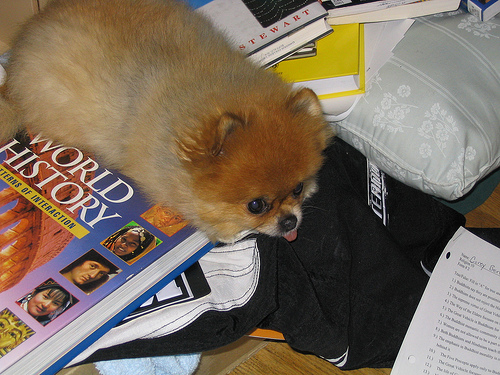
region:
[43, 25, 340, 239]
a small Pomeranian dog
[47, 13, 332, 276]
a dog laying on a pile of clothes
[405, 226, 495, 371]
stapled sheets of printed paper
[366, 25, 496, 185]
a pillow without a pillowcase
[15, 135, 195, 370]
a history book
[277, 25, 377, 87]
a yellow book on a pillow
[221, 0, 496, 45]
a bunch of books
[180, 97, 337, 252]
a dog sticking its tongue out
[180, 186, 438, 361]
a pile of clothes on the floor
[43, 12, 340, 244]
an dog with orange fur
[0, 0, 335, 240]
a small brown dog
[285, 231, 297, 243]
a dogs pink tongue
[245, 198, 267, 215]
round black eye of dog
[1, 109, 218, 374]
a world history book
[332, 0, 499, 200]
a white pillow with flowers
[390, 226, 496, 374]
a peice of white paper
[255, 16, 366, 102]
a yellow text book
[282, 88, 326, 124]
ear of small dog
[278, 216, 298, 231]
nose of the dog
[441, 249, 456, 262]
a hold in the paper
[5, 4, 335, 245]
a tiny brown and white dog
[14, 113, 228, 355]
a hard back school book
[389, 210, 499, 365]
a school paper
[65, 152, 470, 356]
black shorts under a dog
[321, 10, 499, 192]
a white pillow under books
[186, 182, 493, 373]
a buried wood grain desk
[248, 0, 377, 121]
a yellow hard back book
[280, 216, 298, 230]
a black nose on a dog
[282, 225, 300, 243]
a tiny tongue on a tiny dog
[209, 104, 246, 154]
a small dog ear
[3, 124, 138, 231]
World History written on the cover of a book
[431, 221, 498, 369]
White test paper on the floor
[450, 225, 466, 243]
Metal staple on a white paper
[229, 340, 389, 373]
Brown wooden floor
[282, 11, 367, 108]
Yellow book on a pillow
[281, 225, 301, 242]
Red tongue of a dog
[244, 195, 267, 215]
Big black eye of a dog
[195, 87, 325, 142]
Red dog's ears pointed up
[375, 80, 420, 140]
Flower pattern on a white pillow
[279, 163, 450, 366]
Black sweatshirt on the floor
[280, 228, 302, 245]
tiny dog tongue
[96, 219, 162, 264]
picture of a woman's head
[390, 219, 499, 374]
child's homework assignment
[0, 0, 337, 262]
funny looking small dog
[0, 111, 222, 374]
world history textbook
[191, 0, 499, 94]
pile of textbooks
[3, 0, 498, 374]
small dog laying on clutter of textbooks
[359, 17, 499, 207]
light blue pillow with white flower design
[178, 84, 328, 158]
dog's pointy ears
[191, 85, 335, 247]
dog with a tiny face